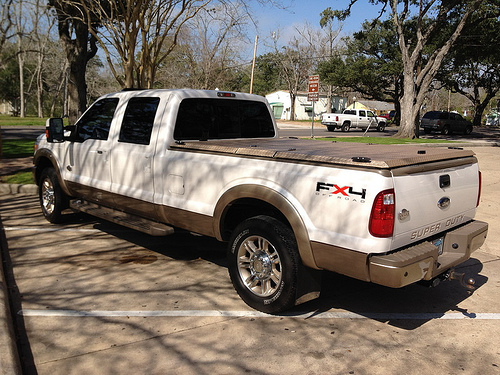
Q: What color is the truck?
A: White.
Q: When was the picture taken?
A: Daytime.